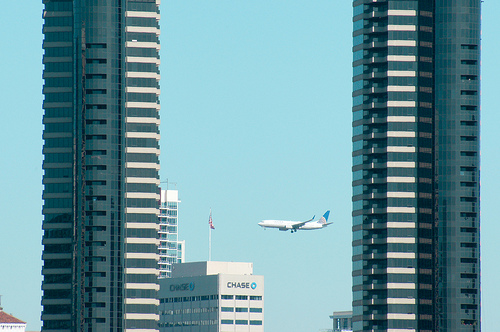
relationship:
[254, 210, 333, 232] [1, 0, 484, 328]
plane in sky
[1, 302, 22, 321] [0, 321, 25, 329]
roof on residence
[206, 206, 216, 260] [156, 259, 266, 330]
flag pole standing on top of bank